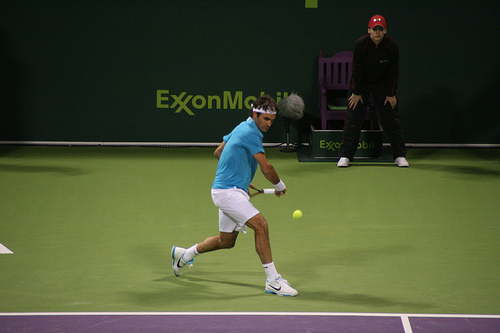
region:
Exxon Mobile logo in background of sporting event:
[126, 85, 313, 119]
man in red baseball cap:
[339, 5, 419, 169]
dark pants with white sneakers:
[326, 105, 414, 181]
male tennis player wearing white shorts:
[163, 92, 319, 300]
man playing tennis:
[187, 95, 308, 220]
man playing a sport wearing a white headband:
[179, 83, 306, 168]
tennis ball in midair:
[257, 170, 324, 253]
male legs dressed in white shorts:
[195, 186, 282, 271]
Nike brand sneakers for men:
[152, 243, 310, 300]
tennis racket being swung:
[214, 168, 311, 230]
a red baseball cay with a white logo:
[361, 8, 394, 49]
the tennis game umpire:
[338, 13, 425, 185]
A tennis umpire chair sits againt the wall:
[305, 42, 362, 159]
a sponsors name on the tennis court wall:
[124, 60, 286, 130]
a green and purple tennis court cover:
[35, 226, 478, 330]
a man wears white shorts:
[190, 176, 271, 260]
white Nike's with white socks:
[163, 234, 321, 304]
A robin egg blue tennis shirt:
[207, 118, 282, 193]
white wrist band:
[253, 166, 296, 197]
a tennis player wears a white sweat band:
[238, 83, 286, 142]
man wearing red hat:
[355, 5, 397, 47]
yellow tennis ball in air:
[287, 194, 327, 248]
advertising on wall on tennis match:
[152, 73, 301, 131]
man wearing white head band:
[243, 88, 282, 143]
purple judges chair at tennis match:
[292, 34, 395, 165]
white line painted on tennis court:
[11, 294, 316, 327]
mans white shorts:
[206, 169, 271, 244]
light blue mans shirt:
[207, 105, 280, 204]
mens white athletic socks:
[234, 248, 359, 321]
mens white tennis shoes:
[262, 271, 304, 303]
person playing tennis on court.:
[86, 42, 417, 315]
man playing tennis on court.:
[90, 75, 420, 307]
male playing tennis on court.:
[110, 65, 405, 310]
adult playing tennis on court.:
[115, 50, 397, 310]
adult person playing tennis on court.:
[121, 80, 371, 297]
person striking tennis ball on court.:
[136, 65, 341, 305]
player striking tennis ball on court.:
[105, 80, 350, 305]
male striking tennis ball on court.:
[111, 71, 352, 316]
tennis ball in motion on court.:
[285, 202, 315, 237]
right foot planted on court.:
[236, 272, 321, 310]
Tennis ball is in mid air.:
[289, 200, 309, 225]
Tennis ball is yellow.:
[286, 204, 308, 224]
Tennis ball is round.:
[288, 203, 305, 222]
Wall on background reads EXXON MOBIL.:
[154, 74, 307, 121]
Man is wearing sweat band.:
[246, 92, 280, 122]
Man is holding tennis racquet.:
[241, 173, 286, 205]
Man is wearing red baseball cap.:
[360, 10, 396, 35]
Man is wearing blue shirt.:
[213, 114, 270, 199]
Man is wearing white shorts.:
[207, 180, 267, 242]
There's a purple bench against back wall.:
[310, 41, 383, 136]